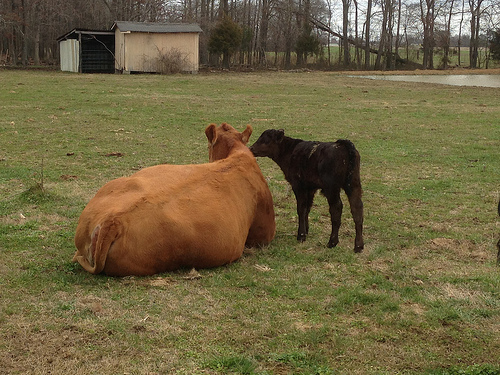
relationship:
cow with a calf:
[48, 82, 285, 297] [248, 101, 378, 238]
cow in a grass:
[69, 124, 276, 278] [2, 67, 499, 375]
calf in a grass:
[249, 128, 363, 252] [2, 67, 499, 375]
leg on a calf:
[342, 179, 364, 254] [247, 117, 389, 257]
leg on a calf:
[322, 185, 343, 248] [247, 117, 389, 257]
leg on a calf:
[300, 186, 321, 246] [247, 117, 389, 257]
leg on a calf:
[293, 186, 309, 241] [247, 117, 389, 257]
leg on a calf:
[326, 185, 343, 249] [251, 128, 367, 253]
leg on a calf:
[347, 179, 369, 259] [251, 128, 367, 253]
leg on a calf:
[293, 186, 309, 241] [251, 128, 367, 253]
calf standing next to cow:
[251, 128, 367, 253] [69, 124, 276, 278]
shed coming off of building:
[68, 19, 118, 73] [118, 30, 199, 74]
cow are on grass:
[69, 124, 276, 278] [2, 67, 484, 373]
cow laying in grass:
[69, 124, 276, 278] [2, 67, 484, 373]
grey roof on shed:
[114, 19, 202, 34] [110, 11, 209, 71]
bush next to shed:
[152, 52, 204, 82] [111, 17, 204, 79]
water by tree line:
[354, 70, 499, 92] [214, 49, 496, 69]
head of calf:
[238, 111, 295, 161] [251, 128, 367, 253]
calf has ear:
[249, 128, 363, 252] [270, 124, 290, 140]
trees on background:
[2, 0, 499, 72] [1, 4, 499, 78]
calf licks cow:
[249, 128, 363, 252] [63, 113, 293, 279]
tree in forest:
[291, 13, 405, 59] [201, 4, 493, 71]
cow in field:
[69, 124, 276, 278] [8, 66, 477, 360]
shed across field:
[110, 20, 206, 76] [8, 66, 477, 360]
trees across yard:
[202, 4, 498, 67] [4, 70, 496, 373]